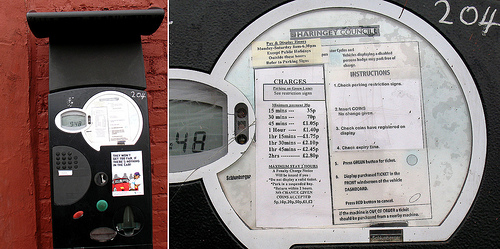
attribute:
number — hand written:
[174, 123, 216, 165]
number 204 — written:
[434, 0, 499, 33]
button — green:
[90, 195, 109, 210]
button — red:
[71, 209, 83, 217]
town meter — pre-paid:
[49, 82, 149, 204]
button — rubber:
[93, 196, 109, 211]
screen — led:
[169, 98, 224, 155]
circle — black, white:
[405, 151, 420, 168]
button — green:
[94, 199, 108, 210]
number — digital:
[173, 127, 210, 159]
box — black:
[48, 35, 155, 247]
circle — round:
[51, 85, 149, 155]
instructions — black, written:
[271, 49, 466, 214]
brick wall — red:
[1, 1, 52, 246]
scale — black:
[201, 36, 392, 183]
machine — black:
[27, 9, 162, 246]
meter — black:
[28, 7, 497, 242]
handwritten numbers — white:
[429, 0, 499, 35]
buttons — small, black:
[54, 150, 78, 169]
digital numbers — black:
[162, 121, 217, 158]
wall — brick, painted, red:
[0, 0, 167, 248]